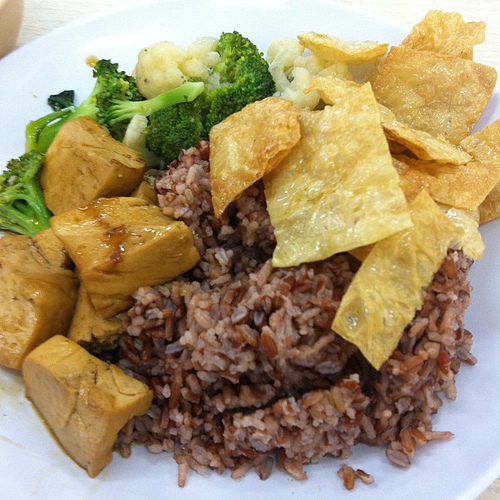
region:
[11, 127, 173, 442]
tan meat on plate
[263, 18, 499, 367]
light brown chips on plate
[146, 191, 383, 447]
brown rice on plate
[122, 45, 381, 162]
white cauliflower on plate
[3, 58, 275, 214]
green broccoli near chicken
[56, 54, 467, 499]
food is on white plate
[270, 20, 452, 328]
chips are on rice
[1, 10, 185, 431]
brown sauce on chicken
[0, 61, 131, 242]
sauce on green broccoli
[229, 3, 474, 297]
crispy chips on plate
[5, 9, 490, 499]
food on white plate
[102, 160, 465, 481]
brown rice on white plate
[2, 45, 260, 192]
bits of broccoli on white plate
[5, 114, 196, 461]
cooked meat on white plate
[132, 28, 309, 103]
white food on white plate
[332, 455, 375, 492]
two stray pieces of rice on white plate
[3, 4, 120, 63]
table white plate is sitting on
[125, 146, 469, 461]
pile of rice on white plate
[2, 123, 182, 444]
five pieces of meat on plate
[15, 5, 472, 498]
empty edges of white plate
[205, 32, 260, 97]
steamed broccoli on lunch plate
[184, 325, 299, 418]
rice on dinner plate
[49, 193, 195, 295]
glazed chicken over rice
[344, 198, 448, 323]
crisp tortilla chips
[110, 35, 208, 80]
steamed side of cauliflower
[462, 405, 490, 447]
edge of a white plate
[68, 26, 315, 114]
side of steamed cauliflower and broccoli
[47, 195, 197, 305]
cubed protein on lunch plate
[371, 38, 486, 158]
crunchy fried tortilla squares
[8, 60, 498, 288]
plate of dinner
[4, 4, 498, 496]
white plate with food on it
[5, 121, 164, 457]
meat on white plate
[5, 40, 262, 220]
broccoli on white plate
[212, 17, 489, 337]
crispy food on white plate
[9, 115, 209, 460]
four chunks of meat on plate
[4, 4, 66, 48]
table white plate is on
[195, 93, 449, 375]
crispy food on top of rice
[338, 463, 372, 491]
two pieces of brown rice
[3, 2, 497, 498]
a white dish with food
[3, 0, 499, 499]
white dish is flat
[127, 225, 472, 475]
a portion of brown rice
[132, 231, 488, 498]
brown rice on side of a dish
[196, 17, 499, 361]
fried tortillas on a white dish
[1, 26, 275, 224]
pieces of broccoli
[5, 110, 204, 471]
meat cut is squares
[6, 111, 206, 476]
white meat with sauce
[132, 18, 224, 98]
a piece of cooked cauliflower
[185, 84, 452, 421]
tortillas over brown rice